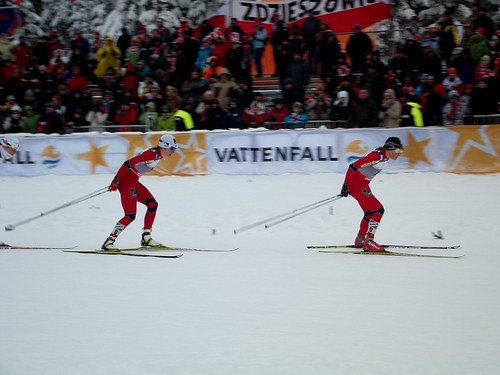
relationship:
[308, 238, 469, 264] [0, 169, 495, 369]
skis are on ground